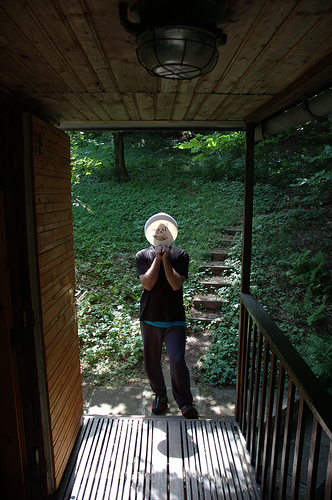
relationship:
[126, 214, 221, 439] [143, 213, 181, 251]
boy holding frisbee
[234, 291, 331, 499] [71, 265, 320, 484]
railing on porch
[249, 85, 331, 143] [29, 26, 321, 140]
gutter coming off roof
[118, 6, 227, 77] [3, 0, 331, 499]
light on porch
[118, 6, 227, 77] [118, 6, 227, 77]
light porch light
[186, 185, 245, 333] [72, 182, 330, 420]
steps on hill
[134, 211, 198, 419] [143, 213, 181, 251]
boy holding frisbee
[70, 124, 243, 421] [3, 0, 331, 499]
edge of porch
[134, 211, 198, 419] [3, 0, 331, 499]
boy by porch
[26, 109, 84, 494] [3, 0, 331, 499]
wall of porch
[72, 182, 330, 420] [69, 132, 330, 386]
green ground covering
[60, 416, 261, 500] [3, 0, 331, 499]
floor of porch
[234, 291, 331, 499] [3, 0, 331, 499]
railing on porch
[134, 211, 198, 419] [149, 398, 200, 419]
boy wearing shoes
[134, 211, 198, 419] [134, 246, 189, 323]
boy black shirt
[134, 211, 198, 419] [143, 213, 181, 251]
boy with frisbee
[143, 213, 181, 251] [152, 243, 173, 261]
frisbee in hands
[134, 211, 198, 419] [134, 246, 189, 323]
boy wearing shirt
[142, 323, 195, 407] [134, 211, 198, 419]
jeans on boy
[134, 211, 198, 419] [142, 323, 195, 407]
boy wearing jeans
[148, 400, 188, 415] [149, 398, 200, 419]
orange on sneakers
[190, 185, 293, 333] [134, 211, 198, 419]
path behind boy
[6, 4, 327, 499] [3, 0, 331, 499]
building made of wood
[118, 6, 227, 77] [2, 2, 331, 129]
light on ceiling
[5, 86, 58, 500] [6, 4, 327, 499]
doorway into building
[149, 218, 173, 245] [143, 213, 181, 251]
colors on frisbee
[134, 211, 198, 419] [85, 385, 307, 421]
boy on sidewalk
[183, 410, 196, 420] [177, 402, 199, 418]
sole of shoe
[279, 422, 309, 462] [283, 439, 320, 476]
part of dish